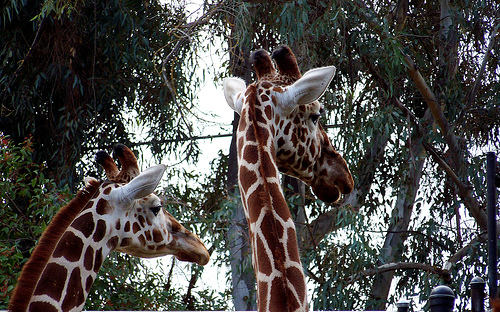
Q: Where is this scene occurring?
A: A zoo.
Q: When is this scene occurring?
A: Dusk.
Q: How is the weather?
A: Cool and clear.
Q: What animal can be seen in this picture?
A: Giraffe.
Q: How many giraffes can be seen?
A: 2.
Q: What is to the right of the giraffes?
A: Fence post.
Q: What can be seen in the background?
A: Trees.